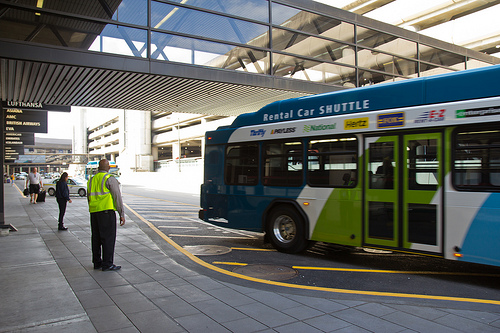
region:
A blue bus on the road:
[191, 60, 498, 277]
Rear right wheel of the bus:
[260, 201, 312, 249]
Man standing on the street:
[82, 156, 127, 273]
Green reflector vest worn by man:
[83, 171, 121, 215]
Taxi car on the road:
[40, 170, 97, 197]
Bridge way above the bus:
[0, 1, 499, 118]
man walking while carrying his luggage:
[21, 164, 47, 205]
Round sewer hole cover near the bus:
[178, 240, 233, 258]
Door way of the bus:
[358, 126, 450, 256]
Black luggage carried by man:
[33, 188, 50, 205]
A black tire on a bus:
[265, 200, 307, 249]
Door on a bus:
[362, 135, 399, 245]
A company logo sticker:
[342, 117, 367, 128]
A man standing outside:
[85, 158, 125, 269]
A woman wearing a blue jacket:
[55, 172, 71, 227]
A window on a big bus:
[224, 142, 259, 184]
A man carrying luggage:
[23, 165, 47, 201]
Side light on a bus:
[451, 253, 463, 258]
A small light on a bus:
[301, 201, 311, 206]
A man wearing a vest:
[87, 156, 124, 271]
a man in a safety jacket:
[85, 157, 130, 270]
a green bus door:
[362, 136, 444, 251]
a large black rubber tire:
[265, 198, 305, 251]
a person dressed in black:
[52, 172, 73, 232]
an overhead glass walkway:
[3, 0, 495, 105]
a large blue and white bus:
[197, 81, 498, 257]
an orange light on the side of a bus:
[300, 198, 310, 207]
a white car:
[44, 175, 91, 198]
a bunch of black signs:
[0, 95, 52, 180]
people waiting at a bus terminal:
[0, 89, 131, 326]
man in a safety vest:
[86, 158, 123, 273]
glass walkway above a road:
[0, 0, 499, 118]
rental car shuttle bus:
[196, 65, 498, 269]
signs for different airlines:
[0, 105, 73, 161]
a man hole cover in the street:
[185, 241, 235, 258]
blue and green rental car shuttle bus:
[196, 62, 496, 272]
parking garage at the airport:
[72, 1, 498, 186]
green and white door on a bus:
[358, 125, 450, 260]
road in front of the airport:
[93, 175, 495, 307]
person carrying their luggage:
[23, 164, 48, 201]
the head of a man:
[81, 148, 121, 188]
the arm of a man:
[93, 169, 148, 231]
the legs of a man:
[82, 211, 157, 279]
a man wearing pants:
[70, 185, 136, 273]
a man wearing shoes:
[77, 243, 155, 286]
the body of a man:
[70, 126, 162, 264]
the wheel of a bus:
[251, 174, 338, 271]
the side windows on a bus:
[223, 128, 403, 200]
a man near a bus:
[67, 82, 384, 271]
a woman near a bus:
[40, 160, 74, 230]